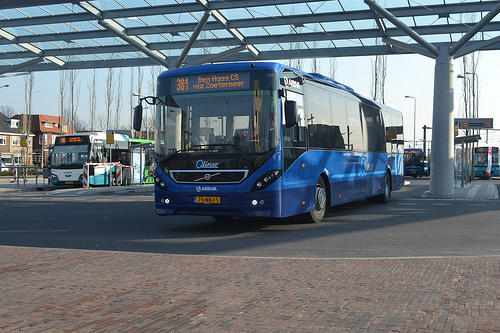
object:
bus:
[132, 61, 403, 222]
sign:
[192, 72, 246, 89]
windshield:
[155, 89, 279, 164]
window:
[274, 87, 355, 126]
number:
[174, 76, 188, 91]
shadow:
[191, 220, 245, 248]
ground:
[140, 233, 244, 288]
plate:
[193, 195, 221, 204]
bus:
[47, 131, 153, 188]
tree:
[78, 64, 138, 131]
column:
[428, 42, 455, 195]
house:
[0, 112, 78, 174]